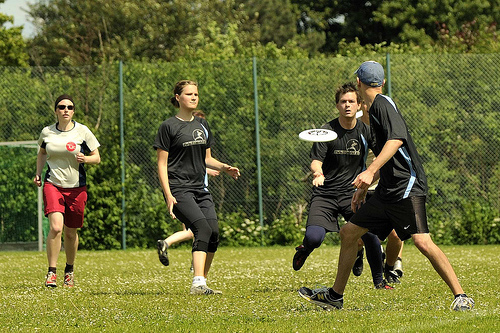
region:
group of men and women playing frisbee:
[29, 58, 485, 308]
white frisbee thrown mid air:
[296, 127, 340, 145]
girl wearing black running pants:
[166, 188, 219, 258]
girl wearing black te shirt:
[158, 117, 218, 192]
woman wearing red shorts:
[41, 180, 88, 228]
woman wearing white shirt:
[38, 123, 101, 188]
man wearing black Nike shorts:
[344, 188, 429, 243]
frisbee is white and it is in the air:
[295, 126, 340, 143]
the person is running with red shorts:
[33, 94, 100, 288]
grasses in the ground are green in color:
[6, 243, 496, 328]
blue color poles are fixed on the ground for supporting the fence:
[8, 52, 497, 244]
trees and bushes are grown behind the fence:
[18, 34, 498, 242]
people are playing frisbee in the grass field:
[31, 58, 474, 320]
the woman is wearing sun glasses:
[32, 95, 101, 287]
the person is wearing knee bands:
[155, 79, 244, 295]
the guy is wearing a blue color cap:
[296, 59, 476, 312]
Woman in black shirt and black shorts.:
[155, 75, 241, 295]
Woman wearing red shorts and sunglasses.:
[31, 94, 101, 291]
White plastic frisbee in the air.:
[294, 127, 337, 142]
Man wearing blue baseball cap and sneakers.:
[297, 59, 479, 311]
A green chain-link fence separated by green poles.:
[1, 52, 497, 238]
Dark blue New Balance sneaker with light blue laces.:
[296, 284, 342, 310]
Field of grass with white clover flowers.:
[0, 249, 498, 331]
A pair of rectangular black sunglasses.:
[52, 102, 72, 109]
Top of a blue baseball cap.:
[355, 59, 385, 85]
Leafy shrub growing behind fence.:
[80, 143, 183, 248]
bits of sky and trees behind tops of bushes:
[5, 5, 494, 72]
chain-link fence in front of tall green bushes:
[7, 46, 496, 249]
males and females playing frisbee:
[30, 57, 471, 314]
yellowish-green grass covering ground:
[5, 244, 495, 327]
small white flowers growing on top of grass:
[3, 251, 490, 323]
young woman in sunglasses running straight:
[27, 95, 104, 290]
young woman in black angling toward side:
[153, 77, 242, 300]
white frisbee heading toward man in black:
[288, 82, 392, 294]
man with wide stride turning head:
[297, 53, 474, 312]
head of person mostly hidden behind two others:
[334, 55, 388, 133]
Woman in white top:
[31, 89, 121, 294]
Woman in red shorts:
[27, 88, 115, 294]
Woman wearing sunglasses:
[22, 85, 109, 297]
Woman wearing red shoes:
[23, 85, 120, 306]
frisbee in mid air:
[299, 125, 339, 147]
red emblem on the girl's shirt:
[66, 143, 76, 151]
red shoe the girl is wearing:
[44, 273, 56, 285]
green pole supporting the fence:
[111, 42, 138, 249]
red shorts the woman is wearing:
[42, 180, 88, 220]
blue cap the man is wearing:
[359, 59, 382, 81]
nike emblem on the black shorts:
[397, 222, 413, 230]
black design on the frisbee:
[308, 128, 323, 136]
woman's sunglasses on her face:
[59, 103, 73, 108]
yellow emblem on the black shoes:
[315, 290, 325, 300]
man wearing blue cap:
[296, 59, 472, 312]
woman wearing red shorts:
[35, 94, 102, 290]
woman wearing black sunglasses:
[32, 95, 99, 285]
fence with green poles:
[3, 52, 494, 245]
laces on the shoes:
[298, 283, 475, 313]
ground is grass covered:
[1, 240, 498, 332]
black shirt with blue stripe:
[368, 92, 429, 197]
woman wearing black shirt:
[153, 80, 239, 295]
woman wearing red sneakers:
[33, 93, 100, 288]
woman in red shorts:
[33, 92, 105, 298]